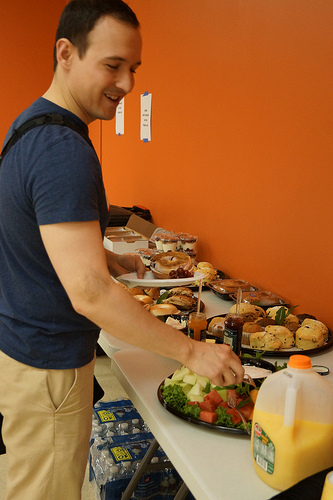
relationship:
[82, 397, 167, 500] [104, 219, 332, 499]
water under table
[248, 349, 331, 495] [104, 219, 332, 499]
gallon on table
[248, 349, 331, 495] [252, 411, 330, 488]
gallon of juice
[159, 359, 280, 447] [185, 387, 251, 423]
tray of fruit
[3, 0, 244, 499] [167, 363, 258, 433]
man selecting food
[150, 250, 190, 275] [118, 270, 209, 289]
bagel on plate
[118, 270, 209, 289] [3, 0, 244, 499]
plate of man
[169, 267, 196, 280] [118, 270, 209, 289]
grapes on plate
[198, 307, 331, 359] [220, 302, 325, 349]
tray of pastries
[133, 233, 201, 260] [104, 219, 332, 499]
parfaits on table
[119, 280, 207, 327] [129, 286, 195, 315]
tray of bagels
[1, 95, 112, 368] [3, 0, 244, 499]
shirt of man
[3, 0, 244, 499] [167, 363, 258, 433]
man grabbing food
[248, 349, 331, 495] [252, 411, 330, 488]
jug of juice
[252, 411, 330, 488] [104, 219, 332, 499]
juice on table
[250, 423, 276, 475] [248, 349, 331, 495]
sticker on jug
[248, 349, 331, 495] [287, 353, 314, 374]
jug has top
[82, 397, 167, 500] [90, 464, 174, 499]
water in packaging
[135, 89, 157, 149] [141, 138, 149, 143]
sign with tape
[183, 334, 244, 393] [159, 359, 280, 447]
hand above platter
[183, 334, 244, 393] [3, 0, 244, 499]
hand of person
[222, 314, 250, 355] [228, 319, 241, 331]
jar of jam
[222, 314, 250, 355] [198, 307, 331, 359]
jar beside plate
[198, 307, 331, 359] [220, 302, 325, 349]
plate of scones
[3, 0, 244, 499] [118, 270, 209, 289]
person holding plate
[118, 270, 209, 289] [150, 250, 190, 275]
plate containing bagel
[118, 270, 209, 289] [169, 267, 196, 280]
plate containing grapes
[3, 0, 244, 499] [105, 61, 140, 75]
man with eyes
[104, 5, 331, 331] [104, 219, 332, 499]
wall behind table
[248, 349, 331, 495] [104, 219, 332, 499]
gallon on counter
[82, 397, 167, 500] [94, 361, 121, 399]
packages on floor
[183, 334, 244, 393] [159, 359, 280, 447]
hand in platter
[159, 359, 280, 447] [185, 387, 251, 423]
platter of fruit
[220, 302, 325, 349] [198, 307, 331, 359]
bread on platter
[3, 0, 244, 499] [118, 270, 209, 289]
man has plate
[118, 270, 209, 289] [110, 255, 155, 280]
plate in hand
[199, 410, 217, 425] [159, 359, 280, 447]
watermelon on platter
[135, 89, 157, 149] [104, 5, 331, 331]
sign on wall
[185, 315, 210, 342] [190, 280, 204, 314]
jellie with spoon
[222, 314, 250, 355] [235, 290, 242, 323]
jellie with spoon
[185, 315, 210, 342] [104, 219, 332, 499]
jellie on table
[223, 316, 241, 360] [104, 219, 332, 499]
jam on table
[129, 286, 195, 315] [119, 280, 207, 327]
bagels on tray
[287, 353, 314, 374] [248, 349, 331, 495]
lid on jug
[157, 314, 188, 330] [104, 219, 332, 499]
cream cheese on table